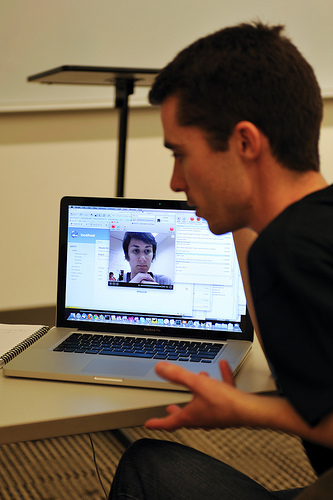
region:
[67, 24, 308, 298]
man sitting in front of computer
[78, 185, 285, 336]
someone on skype talking to other person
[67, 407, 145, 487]
wire under table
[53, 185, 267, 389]
silver laptop open on desk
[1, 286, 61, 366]
notebook next to laptop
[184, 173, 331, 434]
man wearing black shirt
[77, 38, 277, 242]
man with brown hair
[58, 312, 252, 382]
black keys on laptop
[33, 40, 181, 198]
black lamp on pole in background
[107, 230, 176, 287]
This person is thinking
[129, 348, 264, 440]
Hands suggest movement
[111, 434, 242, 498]
Pants are jeans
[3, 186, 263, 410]
Laptop is mac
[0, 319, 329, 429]
The table is supporting a silver macbook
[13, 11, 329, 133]
The ceiling is white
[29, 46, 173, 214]
The lamp post is black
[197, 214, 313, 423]
Man's shirt is black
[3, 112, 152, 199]
The room is white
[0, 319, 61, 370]
There are notes in notebook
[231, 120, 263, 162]
the ear of the man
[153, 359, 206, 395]
the thumb of the man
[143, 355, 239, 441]
the hand of the man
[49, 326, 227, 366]
the black computer keyboard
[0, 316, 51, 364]
a notebook on the table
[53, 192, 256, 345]
a black computer monitor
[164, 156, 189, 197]
the nose of the man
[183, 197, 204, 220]
the mouth of the man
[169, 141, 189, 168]
the eye of the man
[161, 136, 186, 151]
the eyebrow of the man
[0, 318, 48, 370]
a notebook with binding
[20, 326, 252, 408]
grey laptop keyboard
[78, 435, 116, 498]
a black power cord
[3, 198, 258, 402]
a grey laptop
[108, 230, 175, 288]
a face time video on a laptop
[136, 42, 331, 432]
man in black shirt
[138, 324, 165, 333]
logo of laptop company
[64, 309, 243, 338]
taskbar icons on a laptop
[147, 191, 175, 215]
camera light on laptop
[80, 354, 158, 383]
touch pad on a grey laptop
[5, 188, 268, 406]
Laptop is turned on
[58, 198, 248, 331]
Screen of laptop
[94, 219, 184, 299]
Picture of a woman on laptop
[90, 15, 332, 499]
Man has black hair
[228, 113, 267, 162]
Left ear of man can be seen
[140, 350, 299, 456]
Hand is open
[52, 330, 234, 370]
Keyboard of laptop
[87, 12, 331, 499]
Man wears black outfit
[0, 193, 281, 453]
Laptop is over a table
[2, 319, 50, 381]
Notebook next to laptop